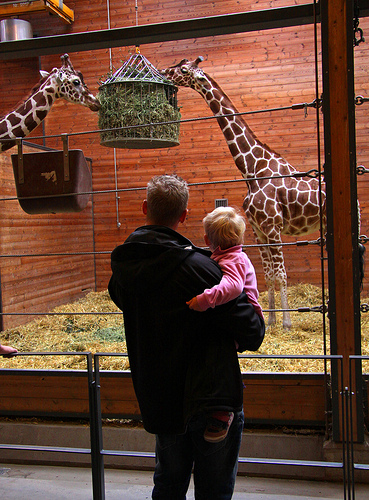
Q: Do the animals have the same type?
A: Yes, all the animals are giraffes.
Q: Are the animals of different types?
A: No, all the animals are giraffes.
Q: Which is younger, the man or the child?
A: The child is younger than the man.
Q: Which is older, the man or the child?
A: The man is older than the child.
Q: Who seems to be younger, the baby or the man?
A: The baby is younger than the man.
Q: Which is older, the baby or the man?
A: The man is older than the baby.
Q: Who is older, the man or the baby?
A: The man is older than the baby.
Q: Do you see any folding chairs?
A: No, there are no folding chairs.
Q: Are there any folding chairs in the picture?
A: No, there are no folding chairs.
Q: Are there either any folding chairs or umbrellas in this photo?
A: No, there are no folding chairs or umbrellas.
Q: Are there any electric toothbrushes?
A: No, there are no electric toothbrushes.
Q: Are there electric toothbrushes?
A: No, there are no electric toothbrushes.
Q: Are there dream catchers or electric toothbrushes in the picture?
A: No, there are no electric toothbrushes or dream catchers.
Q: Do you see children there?
A: Yes, there is a child.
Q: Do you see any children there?
A: Yes, there is a child.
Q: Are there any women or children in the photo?
A: Yes, there is a child.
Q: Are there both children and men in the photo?
A: Yes, there are both a child and a man.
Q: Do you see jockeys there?
A: No, there are no jockeys.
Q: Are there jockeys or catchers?
A: No, there are no jockeys or catchers.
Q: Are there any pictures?
A: No, there are no pictures.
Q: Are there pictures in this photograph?
A: No, there are no pictures.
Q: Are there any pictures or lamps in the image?
A: No, there are no pictures or lamps.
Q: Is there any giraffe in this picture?
A: Yes, there is a giraffe.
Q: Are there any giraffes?
A: Yes, there is a giraffe.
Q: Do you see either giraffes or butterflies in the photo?
A: Yes, there is a giraffe.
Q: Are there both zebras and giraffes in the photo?
A: No, there is a giraffe but no zebras.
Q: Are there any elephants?
A: No, there are no elephants.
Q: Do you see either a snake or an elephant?
A: No, there are no elephants or snakes.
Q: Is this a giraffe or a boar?
A: This is a giraffe.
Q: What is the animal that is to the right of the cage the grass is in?
A: The animal is a giraffe.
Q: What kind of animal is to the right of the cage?
A: The animal is a giraffe.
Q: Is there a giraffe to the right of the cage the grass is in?
A: Yes, there is a giraffe to the right of the cage.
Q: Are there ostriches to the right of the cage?
A: No, there is a giraffe to the right of the cage.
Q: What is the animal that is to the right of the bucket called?
A: The animal is a giraffe.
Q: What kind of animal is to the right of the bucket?
A: The animal is a giraffe.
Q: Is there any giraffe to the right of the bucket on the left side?
A: Yes, there is a giraffe to the right of the bucket.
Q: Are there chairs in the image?
A: No, there are no chairs.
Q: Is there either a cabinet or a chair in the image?
A: No, there are no chairs or cabinets.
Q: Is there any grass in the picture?
A: Yes, there is grass.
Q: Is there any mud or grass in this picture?
A: Yes, there is grass.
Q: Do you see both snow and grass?
A: No, there is grass but no snow.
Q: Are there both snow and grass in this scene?
A: No, there is grass but no snow.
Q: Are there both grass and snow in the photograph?
A: No, there is grass but no snow.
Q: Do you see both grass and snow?
A: No, there is grass but no snow.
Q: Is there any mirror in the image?
A: No, there are no mirrors.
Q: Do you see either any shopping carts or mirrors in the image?
A: No, there are no mirrors or shopping carts.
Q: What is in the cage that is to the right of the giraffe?
A: The grass is in the cage.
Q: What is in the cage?
A: The grass is in the cage.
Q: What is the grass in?
A: The grass is in the cage.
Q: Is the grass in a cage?
A: Yes, the grass is in a cage.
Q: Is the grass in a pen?
A: No, the grass is in a cage.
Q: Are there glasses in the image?
A: No, there are no glasses.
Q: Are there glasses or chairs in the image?
A: No, there are no glasses or chairs.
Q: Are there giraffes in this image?
A: Yes, there is a giraffe.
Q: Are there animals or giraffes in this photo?
A: Yes, there is a giraffe.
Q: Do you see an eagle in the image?
A: No, there are no eagles.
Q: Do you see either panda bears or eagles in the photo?
A: No, there are no eagles or panda bears.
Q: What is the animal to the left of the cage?
A: The animal is a giraffe.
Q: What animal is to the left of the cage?
A: The animal is a giraffe.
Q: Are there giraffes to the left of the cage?
A: Yes, there is a giraffe to the left of the cage.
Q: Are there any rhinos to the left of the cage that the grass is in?
A: No, there is a giraffe to the left of the cage.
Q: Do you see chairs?
A: No, there are no chairs.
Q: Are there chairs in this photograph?
A: No, there are no chairs.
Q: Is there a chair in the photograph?
A: No, there are no chairs.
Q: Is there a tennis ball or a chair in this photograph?
A: No, there are no chairs or tennis balls.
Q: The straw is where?
A: The straw is on the floor.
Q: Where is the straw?
A: The straw is on the floor.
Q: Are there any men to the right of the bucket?
A: Yes, there is a man to the right of the bucket.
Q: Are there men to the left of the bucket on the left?
A: No, the man is to the right of the bucket.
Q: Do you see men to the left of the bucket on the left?
A: No, the man is to the right of the bucket.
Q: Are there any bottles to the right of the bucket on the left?
A: No, there is a man to the right of the bucket.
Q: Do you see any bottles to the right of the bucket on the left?
A: No, there is a man to the right of the bucket.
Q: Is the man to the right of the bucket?
A: Yes, the man is to the right of the bucket.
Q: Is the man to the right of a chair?
A: No, the man is to the right of the bucket.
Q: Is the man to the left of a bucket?
A: No, the man is to the right of a bucket.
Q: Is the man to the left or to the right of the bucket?
A: The man is to the right of the bucket.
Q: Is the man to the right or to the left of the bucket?
A: The man is to the right of the bucket.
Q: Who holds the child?
A: The man holds the child.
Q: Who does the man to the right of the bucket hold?
A: The man holds the child.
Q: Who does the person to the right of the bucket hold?
A: The man holds the child.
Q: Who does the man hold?
A: The man holds the child.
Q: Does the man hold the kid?
A: Yes, the man holds the kid.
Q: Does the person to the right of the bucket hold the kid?
A: Yes, the man holds the kid.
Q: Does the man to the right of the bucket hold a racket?
A: No, the man holds the kid.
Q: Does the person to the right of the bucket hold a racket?
A: No, the man holds the kid.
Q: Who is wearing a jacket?
A: The man is wearing a jacket.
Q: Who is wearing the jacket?
A: The man is wearing a jacket.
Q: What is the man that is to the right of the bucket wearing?
A: The man is wearing a jacket.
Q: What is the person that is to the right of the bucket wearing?
A: The man is wearing a jacket.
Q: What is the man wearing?
A: The man is wearing a jacket.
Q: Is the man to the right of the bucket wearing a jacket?
A: Yes, the man is wearing a jacket.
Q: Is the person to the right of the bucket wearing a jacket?
A: Yes, the man is wearing a jacket.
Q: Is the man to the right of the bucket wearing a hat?
A: No, the man is wearing a jacket.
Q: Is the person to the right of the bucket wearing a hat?
A: No, the man is wearing a jacket.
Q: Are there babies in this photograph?
A: Yes, there is a baby.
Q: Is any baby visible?
A: Yes, there is a baby.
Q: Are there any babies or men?
A: Yes, there is a baby.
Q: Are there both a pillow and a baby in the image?
A: No, there is a baby but no pillows.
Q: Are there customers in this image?
A: No, there are no customers.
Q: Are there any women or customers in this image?
A: No, there are no customers or women.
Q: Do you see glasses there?
A: No, there are no glasses.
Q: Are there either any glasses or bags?
A: No, there are no glasses or bags.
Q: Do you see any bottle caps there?
A: No, there are no bottle caps.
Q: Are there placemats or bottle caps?
A: No, there are no bottle caps or placemats.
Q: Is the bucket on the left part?
A: Yes, the bucket is on the left of the image.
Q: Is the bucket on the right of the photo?
A: No, the bucket is on the left of the image.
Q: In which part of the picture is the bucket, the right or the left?
A: The bucket is on the left of the image.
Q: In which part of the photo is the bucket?
A: The bucket is on the left of the image.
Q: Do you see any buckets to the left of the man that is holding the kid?
A: Yes, there is a bucket to the left of the man.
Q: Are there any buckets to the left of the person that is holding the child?
A: Yes, there is a bucket to the left of the man.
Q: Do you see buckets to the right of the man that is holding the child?
A: No, the bucket is to the left of the man.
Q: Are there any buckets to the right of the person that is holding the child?
A: No, the bucket is to the left of the man.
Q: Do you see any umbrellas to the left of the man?
A: No, there is a bucket to the left of the man.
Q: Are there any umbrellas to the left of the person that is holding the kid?
A: No, there is a bucket to the left of the man.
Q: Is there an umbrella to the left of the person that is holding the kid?
A: No, there is a bucket to the left of the man.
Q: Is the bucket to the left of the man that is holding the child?
A: Yes, the bucket is to the left of the man.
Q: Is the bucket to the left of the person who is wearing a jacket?
A: Yes, the bucket is to the left of the man.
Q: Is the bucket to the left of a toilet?
A: No, the bucket is to the left of the man.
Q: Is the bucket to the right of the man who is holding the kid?
A: No, the bucket is to the left of the man.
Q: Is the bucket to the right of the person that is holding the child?
A: No, the bucket is to the left of the man.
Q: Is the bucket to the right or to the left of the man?
A: The bucket is to the left of the man.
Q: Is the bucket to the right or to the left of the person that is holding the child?
A: The bucket is to the left of the man.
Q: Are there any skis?
A: No, there are no skis.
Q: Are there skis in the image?
A: No, there are no skis.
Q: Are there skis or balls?
A: No, there are no skis or balls.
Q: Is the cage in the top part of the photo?
A: Yes, the cage is in the top of the image.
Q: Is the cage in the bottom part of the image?
A: No, the cage is in the top of the image.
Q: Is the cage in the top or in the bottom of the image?
A: The cage is in the top of the image.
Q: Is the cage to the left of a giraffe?
A: Yes, the cage is to the left of a giraffe.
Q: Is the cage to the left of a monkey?
A: No, the cage is to the left of a giraffe.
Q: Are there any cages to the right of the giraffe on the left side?
A: Yes, there is a cage to the right of the giraffe.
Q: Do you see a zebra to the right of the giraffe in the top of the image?
A: No, there is a cage to the right of the giraffe.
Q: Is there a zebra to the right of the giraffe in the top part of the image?
A: No, there is a cage to the right of the giraffe.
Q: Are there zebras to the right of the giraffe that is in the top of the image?
A: No, there is a cage to the right of the giraffe.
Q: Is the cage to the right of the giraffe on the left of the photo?
A: Yes, the cage is to the right of the giraffe.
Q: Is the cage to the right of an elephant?
A: No, the cage is to the right of the giraffe.